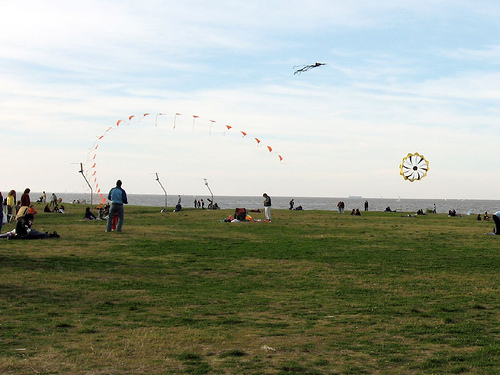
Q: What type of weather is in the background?
A: It is cloudy.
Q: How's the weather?
A: It is cloudy.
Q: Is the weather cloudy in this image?
A: Yes, it is cloudy.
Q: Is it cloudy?
A: Yes, it is cloudy.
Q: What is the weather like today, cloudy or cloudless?
A: It is cloudy.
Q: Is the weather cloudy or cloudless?
A: It is cloudy.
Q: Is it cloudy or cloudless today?
A: It is cloudy.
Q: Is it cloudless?
A: No, it is cloudy.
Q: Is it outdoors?
A: Yes, it is outdoors.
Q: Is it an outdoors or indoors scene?
A: It is outdoors.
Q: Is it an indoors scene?
A: No, it is outdoors.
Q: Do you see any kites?
A: Yes, there is a kite.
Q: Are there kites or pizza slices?
A: Yes, there is a kite.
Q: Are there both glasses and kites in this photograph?
A: No, there is a kite but no glasses.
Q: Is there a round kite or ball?
A: Yes, there is a round kite.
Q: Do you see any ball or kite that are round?
A: Yes, the kite is round.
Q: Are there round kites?
A: Yes, there is a round kite.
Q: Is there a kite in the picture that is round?
A: Yes, there is a kite that is round.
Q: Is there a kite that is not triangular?
A: Yes, there is a round kite.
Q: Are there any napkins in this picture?
A: No, there are no napkins.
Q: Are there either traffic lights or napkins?
A: No, there are no napkins or traffic lights.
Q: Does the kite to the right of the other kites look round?
A: Yes, the kite is round.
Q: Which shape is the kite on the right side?
A: The kite is round.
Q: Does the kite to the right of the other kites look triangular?
A: No, the kite is round.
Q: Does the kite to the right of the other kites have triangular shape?
A: No, the kite is round.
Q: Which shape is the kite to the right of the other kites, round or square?
A: The kite is round.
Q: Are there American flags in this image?
A: No, there are no American flags.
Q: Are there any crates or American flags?
A: No, there are no American flags or crates.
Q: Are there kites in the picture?
A: Yes, there is a kite.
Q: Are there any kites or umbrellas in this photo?
A: Yes, there is a kite.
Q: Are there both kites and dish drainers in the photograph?
A: No, there is a kite but no dish drainers.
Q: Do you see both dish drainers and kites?
A: No, there is a kite but no dish drainers.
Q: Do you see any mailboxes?
A: No, there are no mailboxes.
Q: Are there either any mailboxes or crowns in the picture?
A: No, there are no mailboxes or crowns.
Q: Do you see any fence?
A: No, there are no fences.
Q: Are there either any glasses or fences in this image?
A: No, there are no fences or glasses.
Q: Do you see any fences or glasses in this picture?
A: No, there are no fences or glasses.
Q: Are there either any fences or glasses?
A: No, there are no fences or glasses.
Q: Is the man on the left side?
A: Yes, the man is on the left of the image.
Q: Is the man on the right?
A: No, the man is on the left of the image.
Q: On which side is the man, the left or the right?
A: The man is on the left of the image.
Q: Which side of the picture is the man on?
A: The man is on the left of the image.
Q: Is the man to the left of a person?
A: No, the man is to the right of a person.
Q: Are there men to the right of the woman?
A: Yes, there is a man to the right of the woman.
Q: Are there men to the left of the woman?
A: No, the man is to the right of the woman.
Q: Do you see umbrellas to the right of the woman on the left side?
A: No, there is a man to the right of the woman.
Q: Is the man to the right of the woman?
A: Yes, the man is to the right of the woman.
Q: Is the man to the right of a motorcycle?
A: No, the man is to the right of the woman.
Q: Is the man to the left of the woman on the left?
A: No, the man is to the right of the woman.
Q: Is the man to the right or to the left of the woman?
A: The man is to the right of the woman.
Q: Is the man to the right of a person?
A: No, the man is to the left of a person.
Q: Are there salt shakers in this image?
A: No, there are no salt shakers.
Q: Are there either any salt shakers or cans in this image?
A: No, there are no salt shakers or cans.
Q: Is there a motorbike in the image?
A: No, there are no motorcycles.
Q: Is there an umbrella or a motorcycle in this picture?
A: No, there are no motorcycles or umbrellas.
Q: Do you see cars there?
A: No, there are no cars.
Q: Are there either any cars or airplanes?
A: No, there are no cars or airplanes.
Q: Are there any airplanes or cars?
A: No, there are no cars or airplanes.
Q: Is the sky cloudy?
A: Yes, the sky is cloudy.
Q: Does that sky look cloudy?
A: Yes, the sky is cloudy.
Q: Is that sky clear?
A: No, the sky is cloudy.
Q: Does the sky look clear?
A: No, the sky is cloudy.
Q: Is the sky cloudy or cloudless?
A: The sky is cloudy.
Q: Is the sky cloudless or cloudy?
A: The sky is cloudy.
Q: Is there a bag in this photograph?
A: No, there are no bags.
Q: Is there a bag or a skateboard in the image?
A: No, there are no bags or skateboards.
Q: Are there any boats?
A: No, there are no boats.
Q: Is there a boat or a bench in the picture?
A: No, there are no boats or benches.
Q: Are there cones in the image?
A: No, there are no cones.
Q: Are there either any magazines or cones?
A: No, there are no cones or magazines.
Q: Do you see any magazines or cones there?
A: No, there are no cones or magazines.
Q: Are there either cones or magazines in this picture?
A: No, there are no cones or magazines.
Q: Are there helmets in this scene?
A: No, there are no helmets.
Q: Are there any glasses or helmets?
A: No, there are no helmets or glasses.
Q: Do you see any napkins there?
A: No, there are no napkins.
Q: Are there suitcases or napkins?
A: No, there are no napkins or suitcases.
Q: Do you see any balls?
A: No, there are no balls.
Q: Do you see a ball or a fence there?
A: No, there are no balls or fences.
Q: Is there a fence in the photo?
A: No, there are no fences.